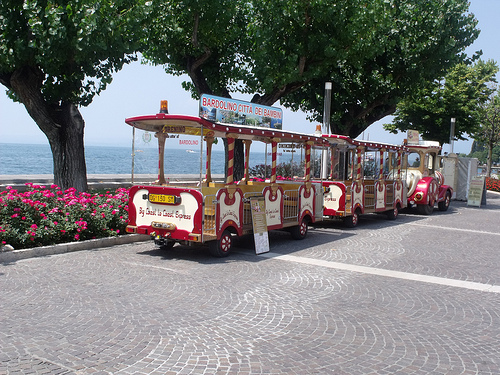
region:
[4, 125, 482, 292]
red and white train car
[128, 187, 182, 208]
yellow plate on front of vehicle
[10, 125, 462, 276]
several vehicles parked on side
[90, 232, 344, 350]
stone ground below vehicles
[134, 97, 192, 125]
small light on top of vehicle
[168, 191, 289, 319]
small sign on side of vehicle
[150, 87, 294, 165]
long sign on top of vehicle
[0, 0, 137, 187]
green leaves on top of tree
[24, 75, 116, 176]
large wooden trunk of tree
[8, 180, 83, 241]
red and green bushes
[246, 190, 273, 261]
Sign next to trolley train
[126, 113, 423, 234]
Trolley train is red and white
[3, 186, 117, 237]
Pink flower bushes next to train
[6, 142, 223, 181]
Calm, serene water in background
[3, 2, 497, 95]
Lush, green trees behind train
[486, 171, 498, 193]
Red flower bush behind train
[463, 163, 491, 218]
Sign standing by train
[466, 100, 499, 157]
Small, skinny tree behind train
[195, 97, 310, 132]
Train has sign on top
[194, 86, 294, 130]
Sign is written in another language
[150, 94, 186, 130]
small orange light on trolly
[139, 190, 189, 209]
a yellow and black license plate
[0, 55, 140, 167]
tree with green leaves and brown trunk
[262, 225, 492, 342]
white line painted on pavement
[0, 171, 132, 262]
flowers that are pink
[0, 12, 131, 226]
flowers water and a tree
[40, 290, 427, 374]
tan bricks in a pattern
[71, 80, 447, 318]
a trolly on the road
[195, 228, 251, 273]
a painted red and white tire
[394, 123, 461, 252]
an old style red and tan car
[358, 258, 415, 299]
white line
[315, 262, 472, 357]
white line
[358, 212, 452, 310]
white line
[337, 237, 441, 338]
white line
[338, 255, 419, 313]
white line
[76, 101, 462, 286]
train on the ground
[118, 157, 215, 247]
front of the train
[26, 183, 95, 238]
flowers next to the train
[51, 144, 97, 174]
branch of the tree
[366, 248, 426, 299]
line on the ground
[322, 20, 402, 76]
tree next to train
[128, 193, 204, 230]
words on the train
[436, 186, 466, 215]
wheel on the train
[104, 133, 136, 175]
water in the distance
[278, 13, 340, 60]
leaves on the tree